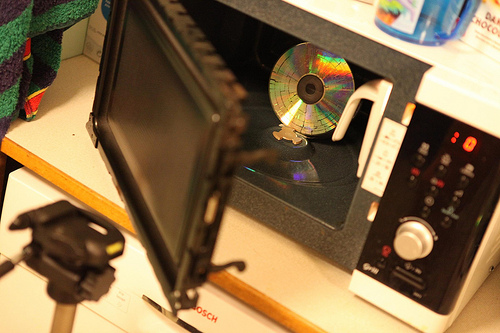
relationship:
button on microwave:
[405, 147, 480, 222] [92, 4, 496, 326]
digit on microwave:
[417, 127, 483, 162] [92, 4, 496, 326]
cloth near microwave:
[6, 10, 78, 131] [92, 4, 496, 326]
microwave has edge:
[92, 4, 496, 326] [299, 238, 433, 332]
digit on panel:
[417, 127, 483, 162] [389, 99, 498, 320]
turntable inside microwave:
[250, 118, 302, 153] [92, 4, 496, 326]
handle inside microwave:
[338, 54, 412, 175] [92, 4, 496, 326]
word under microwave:
[186, 303, 223, 325] [92, 4, 496, 326]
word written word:
[186, 303, 223, 325] [186, 303, 223, 325]